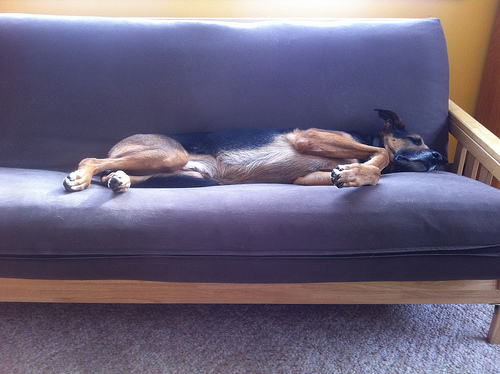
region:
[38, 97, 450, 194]
a dog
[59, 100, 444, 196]
a german shepard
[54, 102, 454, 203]
a dog on a couch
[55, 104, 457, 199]
a dog sleeping on a couch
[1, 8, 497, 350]
the couch has a wood backing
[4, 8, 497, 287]
the couch has a purple cushion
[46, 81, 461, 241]
the dog is sleeping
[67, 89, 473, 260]
the dog is asleep on the couch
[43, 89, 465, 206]
the dog is laying on it's side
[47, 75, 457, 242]
the dog sleeps on a futon couch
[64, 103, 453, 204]
dog laying in his side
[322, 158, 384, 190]
dogs right paw dangling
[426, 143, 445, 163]
puppys black nose on face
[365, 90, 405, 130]
puppys right black ear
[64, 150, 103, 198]
puppys back right paw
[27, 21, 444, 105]
back of purple leather sofa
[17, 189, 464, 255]
front of purple leather sofa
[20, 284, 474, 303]
wooden frame on sofa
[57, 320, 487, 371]
berber carpet in the room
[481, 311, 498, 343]
wooden leg of sofa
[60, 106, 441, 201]
a dog stretched out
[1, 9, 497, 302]
the dog is lying on a sofa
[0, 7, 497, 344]
the sofa frame is wooden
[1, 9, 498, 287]
the sofa cushions are blue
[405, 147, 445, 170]
the dog nose is black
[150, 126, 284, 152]
a black spot on the dog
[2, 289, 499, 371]
carpet on the floor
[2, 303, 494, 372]
the carpet is beige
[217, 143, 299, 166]
white on the dog's stomach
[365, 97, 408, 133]
his ear sticking up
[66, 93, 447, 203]
dog sleeping on a couch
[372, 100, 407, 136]
ear on the dog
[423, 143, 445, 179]
nose on the dog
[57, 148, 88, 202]
paw on the dog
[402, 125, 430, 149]
eye on the dog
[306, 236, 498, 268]
zipper on the cusion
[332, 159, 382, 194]
paw on the dog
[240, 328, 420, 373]
carpet on the floor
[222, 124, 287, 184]
fur on the dog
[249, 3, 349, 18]
sunlight on the wall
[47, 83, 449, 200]
Black, brown and white dog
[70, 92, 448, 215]
Dog streched out on couch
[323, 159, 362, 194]
Black and brown paw of dog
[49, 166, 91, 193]
Black and brown paw of dog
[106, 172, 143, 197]
Black and brown paw of dog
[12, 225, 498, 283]
Line in a couch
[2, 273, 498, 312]
Wooden base of a couch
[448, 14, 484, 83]
Bright yellow wall coloring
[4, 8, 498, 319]
Dog asleep on a couch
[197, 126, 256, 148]
Black fur of a dog